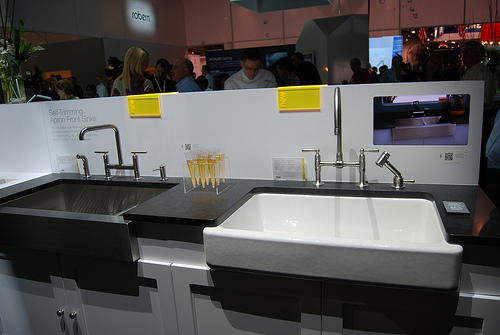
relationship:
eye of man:
[241, 61, 255, 75] [221, 53, 277, 92]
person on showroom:
[348, 34, 403, 92] [0, 0, 499, 332]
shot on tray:
[207, 157, 217, 189] [170, 135, 236, 201]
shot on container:
[207, 157, 217, 189] [183, 146, 231, 194]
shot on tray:
[207, 157, 217, 189] [211, 157, 231, 194]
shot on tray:
[207, 157, 217, 189] [172, 142, 234, 198]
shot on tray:
[207, 157, 217, 189] [179, 147, 231, 193]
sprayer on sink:
[372, 147, 404, 189] [201, 189, 466, 293]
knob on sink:
[300, 142, 324, 181] [225, 150, 472, 290]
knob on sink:
[358, 143, 383, 155] [199, 83, 462, 292]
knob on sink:
[121, 128, 158, 175] [3, 148, 160, 234]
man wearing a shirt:
[221, 53, 277, 92] [223, 69, 278, 88]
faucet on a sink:
[75, 122, 146, 182] [196, 179, 472, 291]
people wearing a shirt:
[109, 46, 155, 97] [118, 64, 182, 106]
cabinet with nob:
[171, 264, 321, 334] [54, 308, 62, 317]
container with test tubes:
[177, 151, 227, 193] [198, 159, 215, 180]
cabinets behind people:
[189, 2, 492, 38] [108, 36, 285, 89]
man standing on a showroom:
[223, 49, 277, 89] [0, 0, 499, 332]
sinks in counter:
[1, 81, 462, 328] [1, 164, 496, 334]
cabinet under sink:
[323, 279, 453, 334] [217, 190, 445, 250]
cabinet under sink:
[171, 263, 327, 334] [217, 190, 445, 250]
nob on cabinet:
[54, 309, 64, 316] [3, 232, 499, 329]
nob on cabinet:
[68, 311, 78, 322] [3, 232, 499, 329]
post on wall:
[128, 86, 328, 118] [2, 87, 492, 177]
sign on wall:
[42, 100, 124, 173] [0, 80, 482, 185]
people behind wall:
[110, 45, 158, 92] [0, 78, 486, 194]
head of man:
[160, 53, 210, 98] [157, 50, 198, 97]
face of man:
[232, 53, 312, 93] [221, 53, 277, 92]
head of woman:
[120, 40, 150, 85] [90, 40, 158, 95]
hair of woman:
[108, 47, 162, 84] [107, 42, 166, 97]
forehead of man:
[241, 57, 265, 82] [218, 45, 278, 93]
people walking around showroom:
[109, 46, 155, 97] [0, 5, 499, 330]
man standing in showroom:
[169, 57, 201, 92] [0, 0, 499, 332]